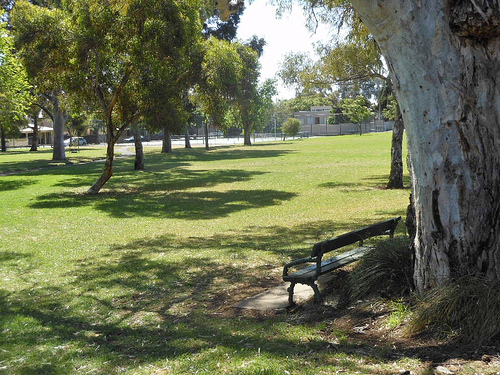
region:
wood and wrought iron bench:
[282, 215, 397, 310]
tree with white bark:
[346, 2, 498, 347]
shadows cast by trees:
[32, 150, 297, 217]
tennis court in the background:
[93, 137, 295, 151]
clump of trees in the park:
[3, 2, 267, 173]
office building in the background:
[291, 105, 397, 136]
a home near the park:
[3, 121, 62, 148]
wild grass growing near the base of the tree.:
[405, 265, 499, 347]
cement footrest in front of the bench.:
[235, 281, 315, 313]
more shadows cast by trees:
[1, 215, 418, 371]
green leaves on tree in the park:
[22, 6, 132, 209]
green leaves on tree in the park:
[112, 10, 163, 182]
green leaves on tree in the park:
[209, 36, 277, 156]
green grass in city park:
[228, 138, 337, 225]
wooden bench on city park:
[268, 211, 413, 319]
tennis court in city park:
[176, 119, 335, 164]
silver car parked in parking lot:
[62, 131, 92, 155]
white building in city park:
[289, 91, 402, 154]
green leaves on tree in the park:
[280, 116, 304, 142]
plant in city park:
[411, 271, 498, 360]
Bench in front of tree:
[260, 201, 440, 313]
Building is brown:
[283, 96, 393, 136]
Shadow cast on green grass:
[7, 217, 270, 372]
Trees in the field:
[0, 0, 277, 177]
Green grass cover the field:
[5, 136, 387, 354]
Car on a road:
[60, 126, 95, 153]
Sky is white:
[247, 9, 327, 69]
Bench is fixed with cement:
[239, 269, 333, 327]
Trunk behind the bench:
[338, 5, 498, 332]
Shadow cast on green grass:
[110, 153, 302, 225]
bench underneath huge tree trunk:
[212, 120, 487, 317]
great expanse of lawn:
[30, 126, 375, 337]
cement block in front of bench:
[220, 237, 360, 318]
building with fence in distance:
[266, 95, 381, 145]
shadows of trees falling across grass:
[51, 127, 326, 237]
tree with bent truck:
[70, 101, 120, 206]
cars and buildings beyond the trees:
[20, 112, 190, 157]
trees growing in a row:
[81, 40, 241, 205]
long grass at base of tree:
[380, 246, 490, 356]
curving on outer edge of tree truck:
[328, 5, 435, 301]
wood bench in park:
[272, 211, 409, 313]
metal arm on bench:
[280, 251, 321, 273]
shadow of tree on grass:
[152, 182, 292, 229]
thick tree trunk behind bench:
[377, 57, 492, 302]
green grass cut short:
[281, 147, 371, 181]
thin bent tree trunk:
[90, 137, 118, 194]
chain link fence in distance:
[260, 129, 287, 145]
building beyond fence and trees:
[293, 101, 340, 127]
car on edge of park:
[55, 134, 92, 153]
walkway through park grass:
[33, 148, 136, 175]